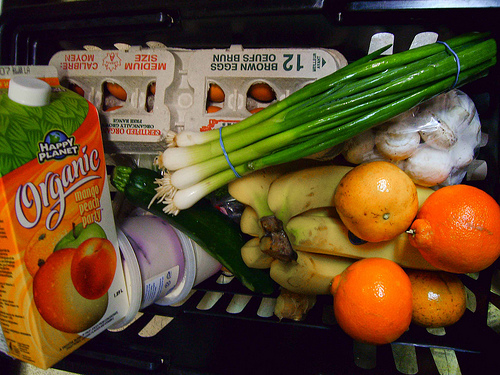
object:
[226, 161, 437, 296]
bunch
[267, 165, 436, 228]
banana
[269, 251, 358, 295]
banana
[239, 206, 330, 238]
banana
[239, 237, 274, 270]
banana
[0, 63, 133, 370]
juice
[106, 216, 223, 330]
two containers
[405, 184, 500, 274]
orange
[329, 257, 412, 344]
orange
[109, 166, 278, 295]
zucchini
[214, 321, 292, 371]
container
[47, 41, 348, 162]
carton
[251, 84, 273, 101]
egg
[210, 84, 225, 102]
egg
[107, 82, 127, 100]
egg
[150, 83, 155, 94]
egg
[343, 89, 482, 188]
mushrooms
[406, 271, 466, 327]
orange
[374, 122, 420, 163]
vegetable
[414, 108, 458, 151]
vegetable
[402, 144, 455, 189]
vegetable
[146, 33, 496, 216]
vegetable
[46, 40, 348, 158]
eggs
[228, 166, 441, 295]
fruits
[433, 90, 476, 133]
mushroom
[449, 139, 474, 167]
mushroom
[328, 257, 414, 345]
tangerine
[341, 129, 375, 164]
mushrooms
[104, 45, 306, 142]
brown table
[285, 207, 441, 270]
banana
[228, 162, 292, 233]
banana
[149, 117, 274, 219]
tan cement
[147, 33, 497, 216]
onions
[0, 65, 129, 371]
carton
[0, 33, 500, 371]
groceries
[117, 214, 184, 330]
tub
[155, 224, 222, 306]
tub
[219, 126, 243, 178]
rubber band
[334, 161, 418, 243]
orange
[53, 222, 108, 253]
apple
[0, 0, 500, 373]
basket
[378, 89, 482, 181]
bag